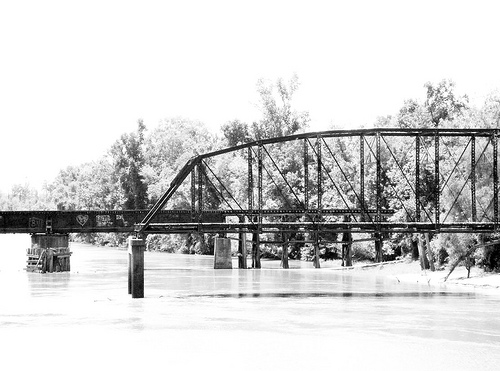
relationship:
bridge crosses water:
[8, 117, 498, 294] [8, 240, 495, 369]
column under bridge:
[27, 232, 70, 272] [8, 117, 498, 294]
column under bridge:
[204, 229, 240, 274] [2, 113, 499, 308]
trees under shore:
[98, 132, 151, 249] [11, 215, 498, 287]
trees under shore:
[98, 132, 151, 229] [11, 215, 498, 287]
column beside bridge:
[123, 237, 151, 297] [8, 117, 498, 294]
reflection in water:
[173, 287, 480, 298] [0, 233, 499, 363]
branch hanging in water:
[423, 245, 483, 282] [8, 240, 495, 369]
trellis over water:
[142, 119, 498, 224] [4, 236, 493, 339]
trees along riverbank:
[98, 132, 151, 249] [73, 236, 125, 262]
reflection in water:
[173, 287, 480, 298] [3, 242, 498, 344]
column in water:
[27, 232, 70, 272] [8, 240, 495, 369]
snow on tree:
[1, 69, 498, 369] [418, 80, 478, 281]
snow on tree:
[1, 69, 498, 369] [218, 77, 328, 268]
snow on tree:
[1, 69, 498, 369] [317, 102, 419, 267]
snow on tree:
[1, 69, 498, 369] [164, 113, 242, 255]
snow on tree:
[1, 69, 498, 369] [93, 117, 163, 249]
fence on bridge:
[192, 135, 495, 218] [8, 117, 498, 294]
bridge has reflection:
[160, 132, 497, 233] [24, 265, 74, 298]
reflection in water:
[24, 265, 74, 298] [21, 256, 496, 367]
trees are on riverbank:
[98, 132, 151, 249] [18, 251, 473, 312]